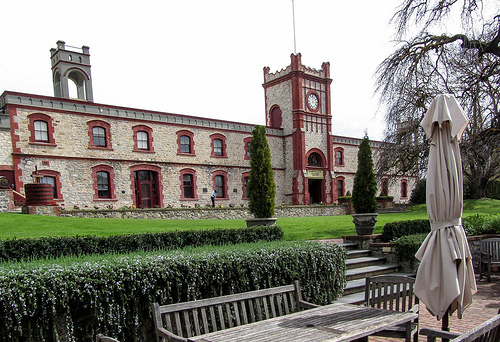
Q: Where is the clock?
A: In the tower.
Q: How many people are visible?
A: 1.